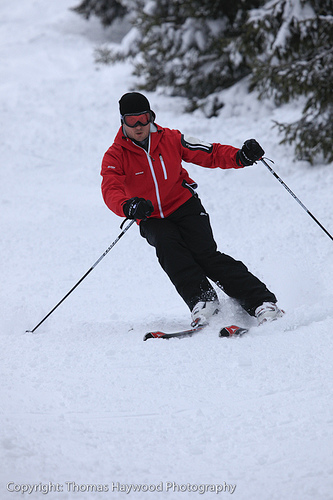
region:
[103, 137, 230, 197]
male skier wearing black, red and white jacket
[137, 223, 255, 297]
male skier wearing black pants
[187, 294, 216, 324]
male skier wearing white boots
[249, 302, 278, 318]
male skier wearing white boots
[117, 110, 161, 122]
male skier wearing black goggles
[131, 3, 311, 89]
green trees covered with white snow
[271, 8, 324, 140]
green trees covered with white snow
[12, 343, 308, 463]
white snow covering ground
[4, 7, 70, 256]
white snow covering ground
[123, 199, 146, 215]
male skier wearing black glove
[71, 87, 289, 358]
A man is skiing.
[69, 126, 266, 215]
The man is wearing a red jacket.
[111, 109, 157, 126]
The man is wearing goggles.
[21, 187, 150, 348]
The man is holding a ski pole in his hand.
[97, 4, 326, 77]
The tree in the background is covered in snow.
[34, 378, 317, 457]
Snow is covering the ground.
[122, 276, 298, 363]
Skis are attached to the man's feet.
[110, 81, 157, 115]
The man has a black hat on his head.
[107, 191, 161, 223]
A glove is covering the man's hand.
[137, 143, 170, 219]
The red jacket has a white zipper.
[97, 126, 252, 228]
the man is wearing a red jacket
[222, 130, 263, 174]
the man is wearing black gloves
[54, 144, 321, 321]
the man is holding ski poles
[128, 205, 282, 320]
the man is wearing black snow pants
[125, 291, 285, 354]
the man has black and red skis on his feet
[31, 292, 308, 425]
snow is covering the ground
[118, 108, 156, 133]
the man is wearing goggles to protect his eyes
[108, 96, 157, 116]
the man is wearing a black hat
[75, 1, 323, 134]
the trees are covered in snow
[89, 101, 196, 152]
the man is looking at the ground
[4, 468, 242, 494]
thomas haywood took this picture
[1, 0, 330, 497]
the snow is white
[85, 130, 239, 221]
man's jacket is red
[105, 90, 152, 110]
man's hat is black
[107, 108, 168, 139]
man is wearing goggles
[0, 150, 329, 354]
man is holding ski poles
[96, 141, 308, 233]
man is wearing black gloves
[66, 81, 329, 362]
the man is skiing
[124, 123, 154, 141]
the man's mouth is open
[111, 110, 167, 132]
goggles on a man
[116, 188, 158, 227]
glove on the man's right hand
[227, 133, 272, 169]
glove on the man's left hand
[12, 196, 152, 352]
stick held in the man's right hand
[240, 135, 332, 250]
stick in the man's left hand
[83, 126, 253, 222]
red jacket the man is wearing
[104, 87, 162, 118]
black hat the man is wearing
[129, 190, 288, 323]
black pants the man is wearing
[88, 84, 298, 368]
a man skiing downhill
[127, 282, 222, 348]
ski on the man's right foot